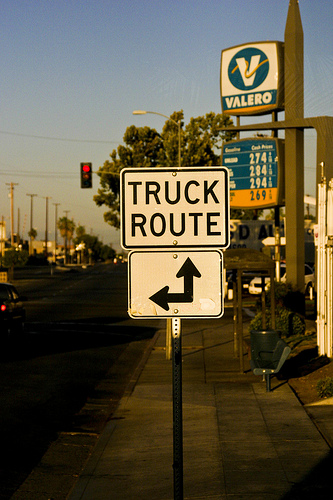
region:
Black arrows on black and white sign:
[147, 255, 204, 312]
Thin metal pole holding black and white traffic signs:
[170, 318, 183, 499]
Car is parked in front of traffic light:
[0, 280, 29, 328]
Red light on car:
[1, 303, 7, 312]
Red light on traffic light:
[82, 164, 88, 172]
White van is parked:
[248, 261, 313, 294]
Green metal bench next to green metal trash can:
[251, 339, 289, 392]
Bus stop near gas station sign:
[216, 250, 276, 375]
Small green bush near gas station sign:
[247, 307, 304, 336]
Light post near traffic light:
[131, 107, 180, 165]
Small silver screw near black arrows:
[173, 253, 178, 260]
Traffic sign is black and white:
[118, 162, 229, 318]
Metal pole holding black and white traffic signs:
[172, 317, 183, 499]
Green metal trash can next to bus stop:
[248, 325, 277, 363]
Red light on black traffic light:
[80, 162, 86, 169]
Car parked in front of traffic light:
[0, 279, 24, 324]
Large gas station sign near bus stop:
[220, 38, 285, 210]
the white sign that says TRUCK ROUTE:
[120, 165, 226, 247]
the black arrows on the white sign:
[146, 255, 201, 311]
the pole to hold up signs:
[168, 316, 187, 497]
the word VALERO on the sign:
[221, 93, 275, 107]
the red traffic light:
[78, 161, 93, 189]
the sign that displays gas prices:
[219, 137, 279, 205]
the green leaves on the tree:
[99, 111, 235, 241]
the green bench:
[249, 340, 289, 393]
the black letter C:
[185, 179, 201, 205]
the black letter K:
[200, 177, 219, 205]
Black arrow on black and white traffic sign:
[147, 256, 202, 312]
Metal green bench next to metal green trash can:
[250, 340, 289, 393]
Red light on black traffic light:
[80, 161, 89, 171]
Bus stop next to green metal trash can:
[218, 247, 277, 376]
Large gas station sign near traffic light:
[216, 40, 284, 211]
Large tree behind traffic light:
[89, 108, 235, 240]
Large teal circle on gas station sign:
[227, 44, 267, 89]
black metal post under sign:
[172, 317, 183, 498]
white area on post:
[171, 317, 182, 336]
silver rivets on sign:
[171, 252, 177, 258]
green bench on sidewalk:
[250, 337, 289, 374]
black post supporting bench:
[265, 372, 271, 385]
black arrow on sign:
[149, 258, 203, 310]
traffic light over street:
[78, 161, 91, 188]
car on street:
[1, 282, 27, 332]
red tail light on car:
[0, 305, 7, 312]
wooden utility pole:
[5, 181, 25, 249]